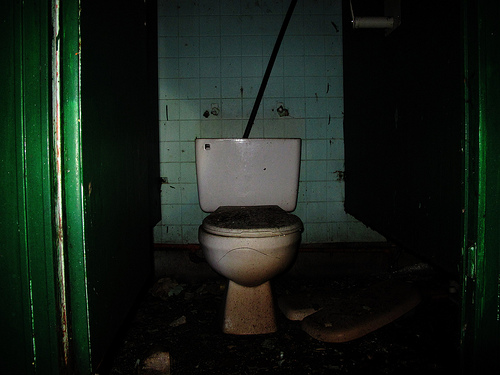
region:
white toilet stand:
[212, 269, 287, 341]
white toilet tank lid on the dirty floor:
[304, 276, 425, 346]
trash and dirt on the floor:
[97, 251, 481, 366]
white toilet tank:
[187, 127, 304, 213]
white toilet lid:
[205, 195, 303, 239]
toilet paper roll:
[345, 15, 402, 32]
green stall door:
[0, 3, 160, 374]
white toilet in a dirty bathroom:
[187, 125, 314, 344]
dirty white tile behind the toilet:
[157, 8, 368, 256]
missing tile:
[271, 102, 291, 119]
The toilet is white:
[168, 119, 323, 335]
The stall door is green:
[339, 16, 468, 263]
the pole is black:
[234, 9, 310, 141]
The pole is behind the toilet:
[184, 14, 301, 341]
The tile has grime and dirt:
[155, 29, 342, 238]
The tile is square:
[164, 46, 347, 261]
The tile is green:
[160, 42, 343, 250]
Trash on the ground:
[132, 282, 213, 369]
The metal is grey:
[343, 12, 405, 37]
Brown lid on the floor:
[299, 268, 427, 346]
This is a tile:
[158, 143, 180, 164]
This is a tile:
[159, 161, 179, 183]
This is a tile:
[159, 183, 181, 204]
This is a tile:
[161, 203, 183, 224]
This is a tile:
[162, 224, 182, 245]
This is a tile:
[158, 78, 179, 99]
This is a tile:
[178, 78, 198, 96]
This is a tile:
[198, 75, 219, 97]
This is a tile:
[220, 75, 242, 98]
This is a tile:
[220, 56, 242, 77]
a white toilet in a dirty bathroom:
[181, 129, 308, 341]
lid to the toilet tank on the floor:
[285, 254, 420, 341]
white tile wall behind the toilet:
[157, 3, 367, 252]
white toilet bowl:
[198, 209, 305, 282]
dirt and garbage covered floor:
[105, 250, 456, 372]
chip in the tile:
[270, 98, 292, 120]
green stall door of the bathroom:
[0, 2, 185, 368]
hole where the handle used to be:
[200, 139, 217, 154]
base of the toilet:
[221, 275, 280, 337]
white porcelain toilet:
[182, 128, 326, 349]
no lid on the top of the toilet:
[190, 121, 315, 161]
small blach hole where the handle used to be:
[202, 140, 214, 153]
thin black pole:
[240, 1, 311, 136]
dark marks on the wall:
[200, 100, 224, 118]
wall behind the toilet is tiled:
[153, 3, 394, 254]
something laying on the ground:
[296, 264, 433, 353]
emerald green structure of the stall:
[7, 6, 169, 373]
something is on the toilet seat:
[197, 197, 301, 237]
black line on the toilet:
[214, 243, 271, 266]